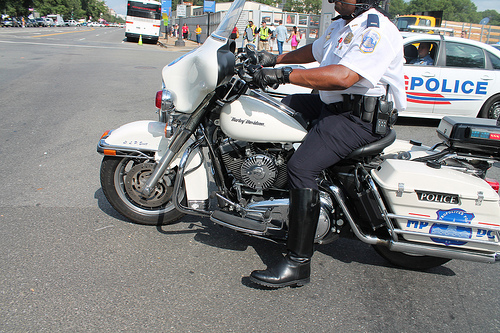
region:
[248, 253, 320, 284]
police wearing black boots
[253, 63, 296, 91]
black gloves on man's hand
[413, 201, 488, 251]
blue symbol on bike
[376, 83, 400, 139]
black walkie talkie on belt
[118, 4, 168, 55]
white bus on the street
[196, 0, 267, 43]
visor on front of bike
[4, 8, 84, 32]
vehicles parked at side of street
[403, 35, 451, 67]
police officers sitting in the car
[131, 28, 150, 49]
yellow cone behind a bus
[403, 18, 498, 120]
large white police car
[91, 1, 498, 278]
a white police motorcycle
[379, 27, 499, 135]
a white police car with red and blue lettering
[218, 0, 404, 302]
a police officer on a motorcycle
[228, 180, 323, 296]
black police boots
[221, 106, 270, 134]
Harley Davidson logo on motorcycle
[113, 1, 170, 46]
a white bus on the side of the road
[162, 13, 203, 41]
people waiting at the bus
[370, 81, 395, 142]
a black police radio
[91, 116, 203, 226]
front tire on a motorcycle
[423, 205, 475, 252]
a blue police shield logo on a motorcycle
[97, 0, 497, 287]
a policeman on a motorcycle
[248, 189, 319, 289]
a policeman's leather boot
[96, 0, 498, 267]
a white police motorcycle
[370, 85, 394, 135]
a police officer's two way radio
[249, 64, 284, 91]
a police officer's left hand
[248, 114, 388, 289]
a police officer's left leg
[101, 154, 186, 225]
front wheel of a motorcycle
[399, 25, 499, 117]
a white police car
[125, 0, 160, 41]
the back of a city bus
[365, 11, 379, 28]
a police officer's shoulder patch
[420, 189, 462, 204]
black and white police sign on motorcycle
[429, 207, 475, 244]
the blue and whit police logo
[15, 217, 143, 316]
part of the gray asphalt street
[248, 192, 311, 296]
a black boot on policeman's foot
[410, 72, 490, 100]
police written on the car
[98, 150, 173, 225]
front wheel on the motorcycle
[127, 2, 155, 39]
back of the white bus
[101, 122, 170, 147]
front white fender on motorcycle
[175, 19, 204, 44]
people walking away from the bus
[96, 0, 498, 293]
a policeman sitting on motorcycle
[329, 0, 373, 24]
head of a person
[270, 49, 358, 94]
arm of a person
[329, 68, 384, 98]
elbow of a person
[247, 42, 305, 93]
hand of a person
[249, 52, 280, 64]
hand of a person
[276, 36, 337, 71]
arm of a person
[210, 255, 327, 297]
feet of a person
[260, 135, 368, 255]
leg of a person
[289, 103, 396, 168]
thigh of a person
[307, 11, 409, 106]
body of a person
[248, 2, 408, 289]
policeman sitting on a motocycle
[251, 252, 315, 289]
black boot the officer is wearing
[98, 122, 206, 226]
front wheel of motorcycle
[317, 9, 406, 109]
white shirt officer is wearing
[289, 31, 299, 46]
pink top woman is wearing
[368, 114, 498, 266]
back of the motorcycle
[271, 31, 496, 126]
white police car in the distance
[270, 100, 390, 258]
black pants the officer is wearing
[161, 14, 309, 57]
people walking in the distance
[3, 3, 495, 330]
a scene on the street